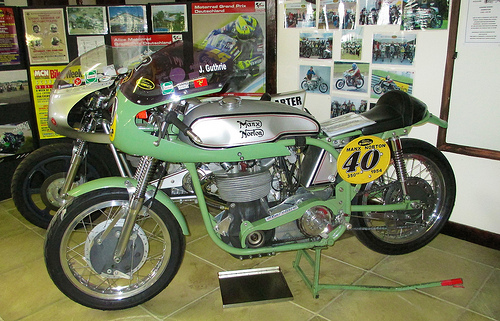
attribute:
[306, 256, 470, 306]
stand — here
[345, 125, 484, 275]
wheel — here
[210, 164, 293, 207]
tank — here, silver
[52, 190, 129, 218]
rubing — rubber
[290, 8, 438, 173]
notice board — here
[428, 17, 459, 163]
edge — wooden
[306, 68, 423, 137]
seat — black, rare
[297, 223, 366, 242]
pedal — here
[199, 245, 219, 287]
floor — tan, here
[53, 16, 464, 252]
motorbike — green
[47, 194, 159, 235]
tube — rubber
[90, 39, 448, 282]
motorcycle — green, here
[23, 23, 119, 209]
motorcycle — silver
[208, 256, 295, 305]
pan — metal